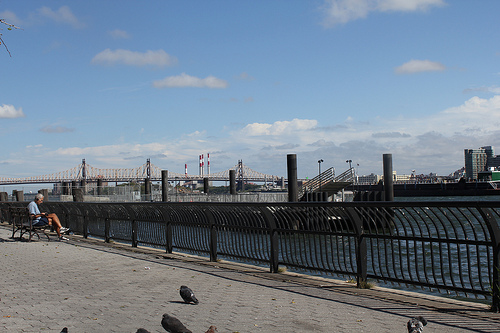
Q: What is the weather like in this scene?
A: It is cloudy.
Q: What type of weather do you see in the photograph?
A: It is cloudy.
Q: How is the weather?
A: It is cloudy.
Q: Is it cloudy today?
A: Yes, it is cloudy.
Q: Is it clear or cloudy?
A: It is cloudy.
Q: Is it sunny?
A: No, it is cloudy.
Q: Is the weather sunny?
A: No, it is cloudy.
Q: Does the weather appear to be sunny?
A: No, it is cloudy.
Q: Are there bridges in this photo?
A: Yes, there is a bridge.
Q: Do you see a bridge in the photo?
A: Yes, there is a bridge.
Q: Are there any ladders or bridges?
A: Yes, there is a bridge.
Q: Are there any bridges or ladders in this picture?
A: Yes, there is a bridge.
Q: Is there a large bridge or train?
A: Yes, there is a large bridge.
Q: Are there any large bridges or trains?
A: Yes, there is a large bridge.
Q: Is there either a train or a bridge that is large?
A: Yes, the bridge is large.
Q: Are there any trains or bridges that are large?
A: Yes, the bridge is large.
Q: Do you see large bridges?
A: Yes, there is a large bridge.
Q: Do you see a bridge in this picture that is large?
A: Yes, there is a bridge that is large.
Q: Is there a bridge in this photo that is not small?
A: Yes, there is a large bridge.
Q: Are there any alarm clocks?
A: No, there are no alarm clocks.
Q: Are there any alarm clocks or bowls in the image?
A: No, there are no alarm clocks or bowls.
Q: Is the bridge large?
A: Yes, the bridge is large.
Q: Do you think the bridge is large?
A: Yes, the bridge is large.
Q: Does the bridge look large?
A: Yes, the bridge is large.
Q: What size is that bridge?
A: The bridge is large.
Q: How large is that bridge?
A: The bridge is large.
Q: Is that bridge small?
A: No, the bridge is large.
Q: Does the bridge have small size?
A: No, the bridge is large.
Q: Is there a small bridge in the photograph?
A: No, there is a bridge but it is large.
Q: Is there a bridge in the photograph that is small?
A: No, there is a bridge but it is large.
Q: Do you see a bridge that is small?
A: No, there is a bridge but it is large.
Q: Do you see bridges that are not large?
A: No, there is a bridge but it is large.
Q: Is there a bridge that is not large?
A: No, there is a bridge but it is large.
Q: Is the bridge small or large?
A: The bridge is large.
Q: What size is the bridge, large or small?
A: The bridge is large.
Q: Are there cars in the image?
A: No, there are no cars.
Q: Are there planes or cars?
A: No, there are no cars or planes.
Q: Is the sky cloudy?
A: Yes, the sky is cloudy.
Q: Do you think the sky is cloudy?
A: Yes, the sky is cloudy.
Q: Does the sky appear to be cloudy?
A: Yes, the sky is cloudy.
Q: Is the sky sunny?
A: No, the sky is cloudy.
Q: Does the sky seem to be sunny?
A: No, the sky is cloudy.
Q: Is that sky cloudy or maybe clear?
A: The sky is cloudy.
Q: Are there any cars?
A: No, there are no cars.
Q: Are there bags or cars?
A: No, there are no cars or bags.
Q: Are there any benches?
A: Yes, there is a bench.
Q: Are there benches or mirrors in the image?
A: Yes, there is a bench.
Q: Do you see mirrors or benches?
A: Yes, there is a bench.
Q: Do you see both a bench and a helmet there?
A: No, there is a bench but no helmets.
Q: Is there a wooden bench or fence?
A: Yes, there is a wood bench.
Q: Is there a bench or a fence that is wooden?
A: Yes, the bench is wooden.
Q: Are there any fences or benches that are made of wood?
A: Yes, the bench is made of wood.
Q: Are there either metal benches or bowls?
A: Yes, there is a metal bench.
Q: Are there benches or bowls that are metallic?
A: Yes, the bench is metallic.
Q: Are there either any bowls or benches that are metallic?
A: Yes, the bench is metallic.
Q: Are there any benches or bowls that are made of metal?
A: Yes, the bench is made of metal.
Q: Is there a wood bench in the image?
A: Yes, there is a wood bench.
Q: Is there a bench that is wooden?
A: Yes, there is a bench that is wooden.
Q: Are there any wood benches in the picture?
A: Yes, there is a bench that is made of wood.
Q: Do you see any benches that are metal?
A: Yes, there is a metal bench.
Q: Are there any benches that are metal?
A: Yes, there is a metal bench.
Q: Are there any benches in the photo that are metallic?
A: Yes, there is a bench that is metallic.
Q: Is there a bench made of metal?
A: Yes, there is a bench that is made of metal.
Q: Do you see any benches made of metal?
A: Yes, there is a bench that is made of metal.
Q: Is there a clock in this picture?
A: No, there are no clocks.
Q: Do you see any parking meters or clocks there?
A: No, there are no clocks or parking meters.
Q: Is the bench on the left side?
A: Yes, the bench is on the left of the image.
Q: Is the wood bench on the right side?
A: No, the bench is on the left of the image.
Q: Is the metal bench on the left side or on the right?
A: The bench is on the left of the image.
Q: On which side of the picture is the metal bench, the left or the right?
A: The bench is on the left of the image.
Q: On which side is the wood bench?
A: The bench is on the left of the image.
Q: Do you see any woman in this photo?
A: No, there are no women.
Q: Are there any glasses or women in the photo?
A: No, there are no women or glasses.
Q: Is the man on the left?
A: Yes, the man is on the left of the image.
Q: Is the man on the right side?
A: No, the man is on the left of the image.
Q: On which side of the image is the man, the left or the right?
A: The man is on the left of the image.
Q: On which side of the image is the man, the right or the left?
A: The man is on the left of the image.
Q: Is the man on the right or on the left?
A: The man is on the left of the image.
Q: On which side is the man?
A: The man is on the left of the image.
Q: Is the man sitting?
A: Yes, the man is sitting.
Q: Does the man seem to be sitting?
A: Yes, the man is sitting.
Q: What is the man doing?
A: The man is sitting.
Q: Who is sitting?
A: The man is sitting.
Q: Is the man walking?
A: No, the man is sitting.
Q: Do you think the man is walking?
A: No, the man is sitting.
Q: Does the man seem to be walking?
A: No, the man is sitting.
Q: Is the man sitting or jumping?
A: The man is sitting.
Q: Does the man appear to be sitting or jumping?
A: The man is sitting.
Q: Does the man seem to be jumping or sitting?
A: The man is sitting.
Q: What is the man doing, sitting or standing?
A: The man is sitting.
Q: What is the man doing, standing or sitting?
A: The man is sitting.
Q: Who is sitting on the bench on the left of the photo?
A: The man is sitting on the bench.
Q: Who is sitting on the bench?
A: The man is sitting on the bench.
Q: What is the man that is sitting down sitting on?
A: The man is sitting on the bench.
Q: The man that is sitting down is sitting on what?
A: The man is sitting on the bench.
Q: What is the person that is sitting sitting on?
A: The man is sitting on the bench.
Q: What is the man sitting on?
A: The man is sitting on the bench.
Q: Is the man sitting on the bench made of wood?
A: Yes, the man is sitting on the bench.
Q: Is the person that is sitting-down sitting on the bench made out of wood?
A: Yes, the man is sitting on the bench.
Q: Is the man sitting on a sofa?
A: No, the man is sitting on the bench.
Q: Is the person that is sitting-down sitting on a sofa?
A: No, the man is sitting on the bench.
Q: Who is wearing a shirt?
A: The man is wearing a shirt.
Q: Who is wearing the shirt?
A: The man is wearing a shirt.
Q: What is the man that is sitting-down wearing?
A: The man is wearing a shirt.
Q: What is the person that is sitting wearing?
A: The man is wearing a shirt.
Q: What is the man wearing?
A: The man is wearing a shirt.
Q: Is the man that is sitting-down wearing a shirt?
A: Yes, the man is wearing a shirt.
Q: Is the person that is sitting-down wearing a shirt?
A: Yes, the man is wearing a shirt.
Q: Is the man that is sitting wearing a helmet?
A: No, the man is wearing a shirt.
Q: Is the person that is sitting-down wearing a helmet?
A: No, the man is wearing a shirt.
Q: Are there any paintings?
A: No, there are no paintings.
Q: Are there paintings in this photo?
A: No, there are no paintings.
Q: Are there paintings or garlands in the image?
A: No, there are no paintings or garlands.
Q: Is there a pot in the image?
A: No, there are no pots.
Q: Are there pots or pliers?
A: No, there are no pots or pliers.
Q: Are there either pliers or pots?
A: No, there are no pots or pliers.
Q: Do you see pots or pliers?
A: No, there are no pots or pliers.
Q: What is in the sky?
A: The clouds are in the sky.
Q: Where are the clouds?
A: The clouds are in the sky.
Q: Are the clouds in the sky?
A: Yes, the clouds are in the sky.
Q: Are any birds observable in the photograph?
A: Yes, there is a bird.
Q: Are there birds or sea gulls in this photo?
A: Yes, there is a bird.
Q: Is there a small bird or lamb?
A: Yes, there is a small bird.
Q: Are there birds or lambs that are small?
A: Yes, the bird is small.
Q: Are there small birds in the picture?
A: Yes, there is a small bird.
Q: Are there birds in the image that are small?
A: Yes, there is a bird that is small.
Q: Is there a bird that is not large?
A: Yes, there is a small bird.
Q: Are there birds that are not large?
A: Yes, there is a small bird.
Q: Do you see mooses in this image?
A: No, there are no mooses.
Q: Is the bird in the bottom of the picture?
A: Yes, the bird is in the bottom of the image.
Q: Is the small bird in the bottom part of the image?
A: Yes, the bird is in the bottom of the image.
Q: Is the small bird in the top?
A: No, the bird is in the bottom of the image.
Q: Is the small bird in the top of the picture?
A: No, the bird is in the bottom of the image.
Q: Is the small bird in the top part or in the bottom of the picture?
A: The bird is in the bottom of the image.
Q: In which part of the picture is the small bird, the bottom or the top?
A: The bird is in the bottom of the image.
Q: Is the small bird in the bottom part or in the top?
A: The bird is in the bottom of the image.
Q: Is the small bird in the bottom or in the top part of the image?
A: The bird is in the bottom of the image.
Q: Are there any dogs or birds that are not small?
A: No, there is a bird but it is small.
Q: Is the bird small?
A: Yes, the bird is small.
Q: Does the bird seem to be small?
A: Yes, the bird is small.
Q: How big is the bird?
A: The bird is small.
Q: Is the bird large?
A: No, the bird is small.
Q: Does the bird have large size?
A: No, the bird is small.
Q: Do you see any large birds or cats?
A: No, there is a bird but it is small.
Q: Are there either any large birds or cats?
A: No, there is a bird but it is small.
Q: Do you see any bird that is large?
A: No, there is a bird but it is small.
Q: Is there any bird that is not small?
A: No, there is a bird but it is small.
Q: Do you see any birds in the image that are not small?
A: No, there is a bird but it is small.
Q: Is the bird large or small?
A: The bird is small.